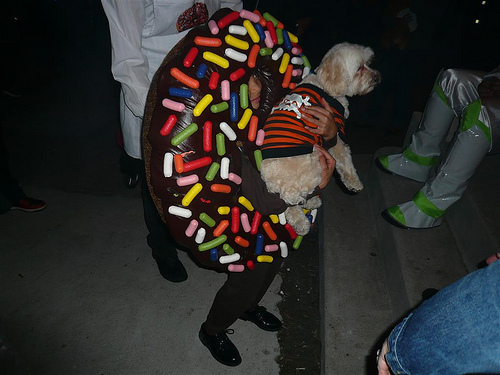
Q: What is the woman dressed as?
A: A donut.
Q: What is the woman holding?
A: A dog.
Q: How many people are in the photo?
A: Three.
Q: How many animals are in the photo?
A: One.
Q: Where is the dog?
A: In the woman's hand.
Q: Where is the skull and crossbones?
A: On the dog.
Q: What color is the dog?
A: White.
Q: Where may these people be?
A: A costume party.